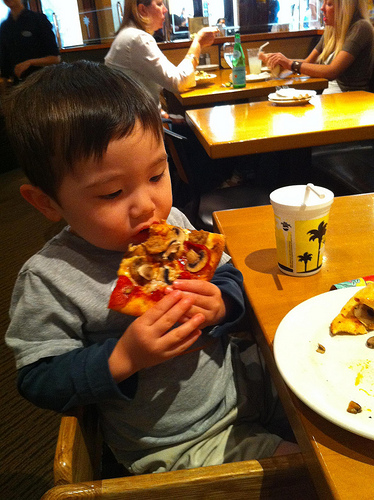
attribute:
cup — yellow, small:
[263, 168, 320, 308]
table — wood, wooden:
[227, 188, 354, 499]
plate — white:
[270, 288, 372, 483]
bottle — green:
[219, 39, 260, 107]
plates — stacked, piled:
[271, 74, 318, 106]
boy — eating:
[19, 53, 308, 480]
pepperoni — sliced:
[107, 277, 139, 307]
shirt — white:
[103, 23, 201, 96]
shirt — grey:
[41, 213, 266, 478]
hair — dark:
[1, 58, 143, 185]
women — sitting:
[100, 9, 371, 110]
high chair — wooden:
[17, 398, 333, 499]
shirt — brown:
[303, 29, 372, 87]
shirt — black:
[2, 18, 56, 83]